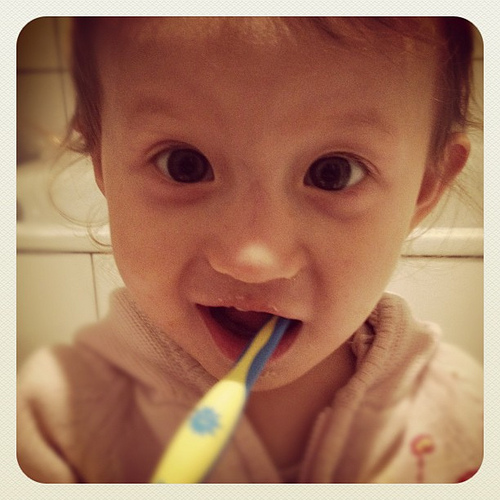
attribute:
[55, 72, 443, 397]
child — looking, brushing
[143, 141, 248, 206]
eye — big, brow, large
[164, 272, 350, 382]
mouth — kid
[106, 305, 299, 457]
brush — tooth, yellow, blue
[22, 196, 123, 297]
counter — white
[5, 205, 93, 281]
pattern — red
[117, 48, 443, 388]
kid — little, brushing, yellow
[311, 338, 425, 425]
piece — smal, small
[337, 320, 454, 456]
robe — bath